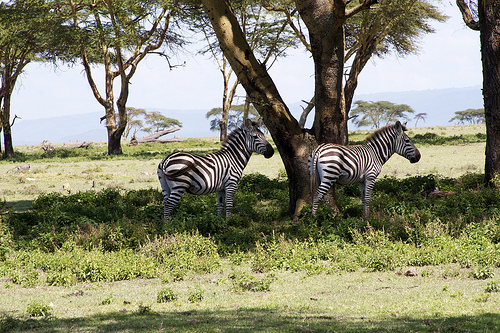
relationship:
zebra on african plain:
[157, 117, 274, 221] [1, 121, 498, 221]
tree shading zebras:
[173, 27, 484, 276] [87, 107, 434, 232]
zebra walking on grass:
[308, 121, 421, 218] [0, 122, 499, 332]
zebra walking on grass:
[155, 112, 276, 228] [0, 122, 499, 332]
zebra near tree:
[157, 117, 274, 221] [197, 1, 436, 211]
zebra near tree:
[308, 121, 421, 218] [197, 1, 436, 211]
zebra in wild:
[157, 117, 274, 221] [41, 36, 479, 310]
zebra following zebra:
[308, 115, 422, 225] [149, 115, 279, 235]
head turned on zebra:
[233, 115, 275, 160] [149, 115, 279, 235]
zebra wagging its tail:
[157, 117, 274, 221] [152, 155, 206, 173]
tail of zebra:
[290, 159, 328, 209] [297, 112, 437, 227]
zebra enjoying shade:
[155, 112, 276, 228] [1, 170, 499, 258]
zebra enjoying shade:
[308, 121, 421, 218] [2, 175, 496, 245]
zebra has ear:
[157, 117, 274, 221] [244, 119, 254, 131]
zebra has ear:
[157, 117, 274, 221] [254, 114, 266, 129]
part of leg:
[306, 177, 335, 227] [309, 173, 339, 221]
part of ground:
[304, 283, 325, 304] [3, 127, 498, 330]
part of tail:
[305, 179, 321, 196] [296, 141, 331, 216]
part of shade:
[470, 316, 493, 331] [401, 315, 496, 331]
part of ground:
[289, 296, 320, 315] [232, 263, 365, 324]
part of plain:
[139, 258, 183, 288] [1, 132, 493, 332]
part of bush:
[44, 149, 73, 155] [31, 135, 104, 167]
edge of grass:
[3, 320, 498, 330] [0, 123, 500, 333]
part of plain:
[27, 239, 57, 269] [2, 143, 154, 329]